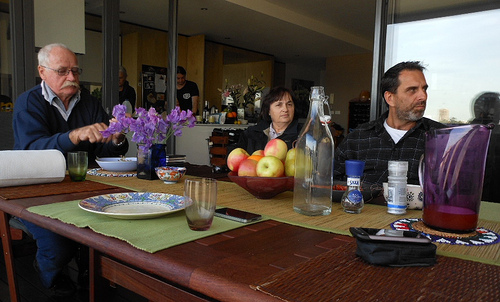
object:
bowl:
[228, 177, 294, 200]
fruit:
[224, 138, 299, 178]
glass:
[180, 177, 218, 232]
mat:
[118, 218, 189, 240]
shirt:
[41, 80, 82, 122]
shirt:
[229, 124, 299, 151]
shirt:
[335, 115, 425, 185]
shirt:
[176, 81, 201, 113]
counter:
[222, 227, 338, 277]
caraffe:
[293, 85, 336, 217]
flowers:
[98, 106, 194, 151]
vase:
[136, 143, 167, 181]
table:
[76, 229, 355, 302]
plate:
[76, 190, 194, 221]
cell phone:
[347, 225, 435, 244]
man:
[8, 42, 131, 173]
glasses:
[39, 65, 83, 77]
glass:
[66, 151, 89, 183]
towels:
[0, 148, 68, 186]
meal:
[99, 157, 138, 161]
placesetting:
[42, 179, 219, 252]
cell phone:
[211, 206, 264, 225]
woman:
[234, 87, 302, 155]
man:
[331, 60, 452, 185]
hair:
[37, 45, 52, 66]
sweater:
[13, 90, 125, 163]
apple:
[237, 159, 257, 178]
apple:
[255, 156, 284, 178]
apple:
[263, 139, 288, 160]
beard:
[396, 110, 414, 120]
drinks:
[419, 205, 477, 231]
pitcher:
[421, 121, 493, 235]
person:
[175, 66, 202, 112]